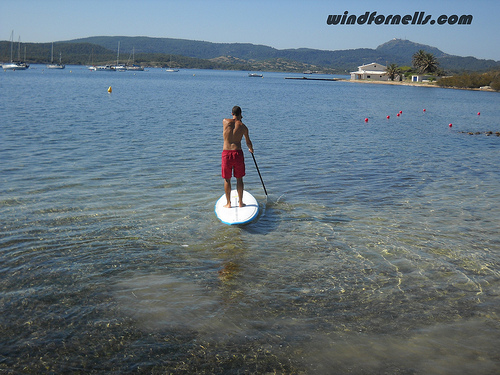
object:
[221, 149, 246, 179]
shorts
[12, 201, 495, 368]
sea grass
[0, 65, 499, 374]
ocean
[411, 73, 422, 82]
gazebo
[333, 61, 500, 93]
island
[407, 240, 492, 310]
wave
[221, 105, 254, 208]
man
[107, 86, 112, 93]
buoy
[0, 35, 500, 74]
mountain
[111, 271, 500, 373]
shallow water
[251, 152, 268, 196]
paddle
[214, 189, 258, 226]
board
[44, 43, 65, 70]
sailboat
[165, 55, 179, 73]
sailboat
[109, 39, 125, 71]
sailboat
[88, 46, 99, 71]
sailboat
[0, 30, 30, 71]
sailboat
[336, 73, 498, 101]
sea shore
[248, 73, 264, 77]
boat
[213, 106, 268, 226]
paddleboard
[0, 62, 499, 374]
water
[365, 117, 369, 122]
buoy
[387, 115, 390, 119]
buoy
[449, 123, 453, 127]
buoy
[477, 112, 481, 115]
buoy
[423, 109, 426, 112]
buoy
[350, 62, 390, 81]
house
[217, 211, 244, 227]
stripe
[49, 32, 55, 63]
sails